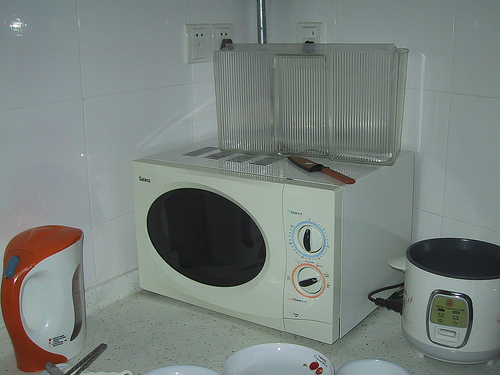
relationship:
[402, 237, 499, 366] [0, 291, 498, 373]
slow cooker on counter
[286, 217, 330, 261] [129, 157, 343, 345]
control knob beside microwave's door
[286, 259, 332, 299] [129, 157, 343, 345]
control knob beside microwave's door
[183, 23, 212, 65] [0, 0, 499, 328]
electrical outlet on wall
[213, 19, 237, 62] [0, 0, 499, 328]
electrical outlet on wall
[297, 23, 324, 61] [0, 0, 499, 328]
electrical outlet on wall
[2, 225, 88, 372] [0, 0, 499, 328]
pitcher against wall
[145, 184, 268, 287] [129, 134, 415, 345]
window on microwave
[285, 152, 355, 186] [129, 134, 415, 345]
knife on top of microwave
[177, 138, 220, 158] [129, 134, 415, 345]
vent on top of microwave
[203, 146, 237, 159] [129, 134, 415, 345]
vent on top of microwave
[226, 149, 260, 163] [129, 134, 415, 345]
vent on top of microwave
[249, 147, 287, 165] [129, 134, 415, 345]
vent on top of microwave